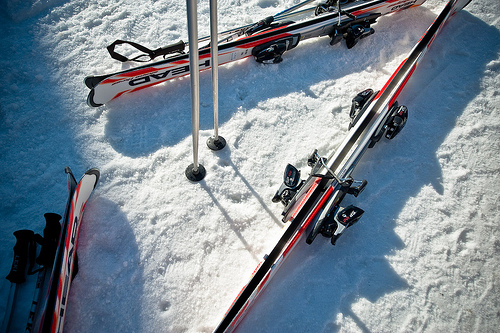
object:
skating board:
[207, 0, 475, 332]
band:
[110, 34, 154, 64]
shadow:
[105, 0, 437, 149]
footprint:
[139, 216, 199, 278]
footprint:
[233, 116, 285, 181]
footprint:
[87, 181, 139, 236]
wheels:
[182, 159, 207, 180]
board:
[84, 0, 422, 107]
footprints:
[411, 237, 483, 293]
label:
[129, 59, 211, 86]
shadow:
[233, 6, 500, 332]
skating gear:
[7, 162, 100, 330]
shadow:
[180, 183, 256, 264]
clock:
[256, 11, 398, 194]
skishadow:
[241, 2, 496, 330]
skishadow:
[98, 10, 437, 165]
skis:
[0, 162, 101, 333]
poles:
[0, 228, 40, 333]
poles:
[186, 0, 207, 180]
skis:
[77, 0, 431, 106]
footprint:
[440, 222, 477, 263]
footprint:
[453, 271, 490, 329]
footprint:
[401, 282, 438, 331]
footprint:
[396, 225, 423, 263]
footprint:
[491, 255, 498, 305]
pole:
[209, 0, 219, 149]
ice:
[442, 232, 494, 287]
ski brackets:
[269, 148, 368, 246]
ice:
[140, 205, 188, 245]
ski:
[80, 2, 425, 105]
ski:
[45, 162, 99, 328]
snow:
[1, 0, 497, 331]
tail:
[80, 54, 191, 106]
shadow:
[223, 150, 292, 230]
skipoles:
[183, 0, 228, 185]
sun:
[137, 171, 207, 240]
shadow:
[0, 0, 144, 333]